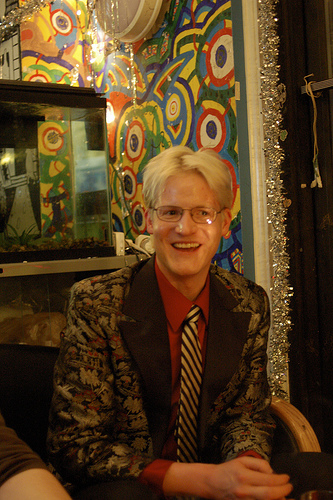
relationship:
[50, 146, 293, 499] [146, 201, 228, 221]
man in glasses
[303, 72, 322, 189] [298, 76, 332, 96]
tinsel on handle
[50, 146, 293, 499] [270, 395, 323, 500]
man on chair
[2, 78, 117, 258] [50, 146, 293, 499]
fish tank behind man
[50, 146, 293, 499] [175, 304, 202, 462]
man with tie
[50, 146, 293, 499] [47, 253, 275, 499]
man in jacket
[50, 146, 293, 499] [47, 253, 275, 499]
man with jacket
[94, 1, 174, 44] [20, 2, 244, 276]
clock on wall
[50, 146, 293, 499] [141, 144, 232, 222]
man has hair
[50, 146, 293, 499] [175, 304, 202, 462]
man in tie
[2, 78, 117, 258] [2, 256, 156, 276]
fish tank on table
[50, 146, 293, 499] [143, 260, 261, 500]
man in shirt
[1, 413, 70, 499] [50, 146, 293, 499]
arm next to man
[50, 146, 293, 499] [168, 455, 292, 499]
man with hands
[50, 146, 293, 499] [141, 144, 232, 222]
man with hair